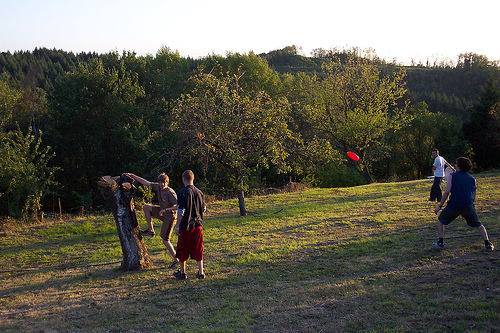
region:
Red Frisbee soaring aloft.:
[323, 131, 374, 185]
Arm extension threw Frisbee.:
[420, 140, 459, 216]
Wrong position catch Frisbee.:
[430, 158, 487, 266]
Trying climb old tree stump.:
[100, 165, 176, 276]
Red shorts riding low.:
[176, 170, 212, 281]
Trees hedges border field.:
[85, 63, 411, 190]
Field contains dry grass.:
[248, 195, 430, 321]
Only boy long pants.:
[416, 142, 453, 221]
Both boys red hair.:
[133, 165, 209, 191]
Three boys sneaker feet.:
[135, 224, 497, 284]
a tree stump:
[96, 173, 156, 270]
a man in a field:
[173, 165, 222, 289]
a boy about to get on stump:
[114, 154, 182, 257]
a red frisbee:
[342, 136, 363, 172]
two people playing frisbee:
[420, 141, 498, 274]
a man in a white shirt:
[426, 143, 453, 180]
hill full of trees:
[12, 34, 337, 153]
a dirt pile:
[276, 179, 314, 193]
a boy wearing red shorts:
[174, 165, 210, 297]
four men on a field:
[96, 144, 488, 286]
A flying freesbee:
[336, 140, 382, 198]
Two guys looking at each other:
[79, 150, 256, 259]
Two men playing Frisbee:
[331, 88, 492, 273]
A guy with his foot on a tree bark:
[87, 166, 175, 247]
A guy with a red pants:
[181, 168, 214, 297]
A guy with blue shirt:
[451, 157, 488, 262]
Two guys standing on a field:
[101, 154, 258, 291]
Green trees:
[35, 51, 374, 166]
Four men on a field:
[41, 82, 493, 319]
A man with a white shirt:
[418, 143, 445, 183]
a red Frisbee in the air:
[343, 149, 362, 164]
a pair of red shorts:
[173, 222, 205, 265]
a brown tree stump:
[96, 168, 158, 272]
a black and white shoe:
[431, 234, 448, 250]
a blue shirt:
[446, 170, 477, 206]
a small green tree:
[163, 60, 302, 219]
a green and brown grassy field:
[2, 167, 497, 331]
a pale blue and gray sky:
[1, 1, 498, 69]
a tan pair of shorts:
[143, 203, 176, 240]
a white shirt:
[430, 155, 450, 179]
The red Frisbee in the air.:
[343, 148, 364, 165]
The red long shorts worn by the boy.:
[178, 229, 205, 261]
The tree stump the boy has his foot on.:
[101, 171, 156, 272]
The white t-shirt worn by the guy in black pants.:
[426, 155, 446, 178]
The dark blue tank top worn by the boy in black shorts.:
[446, 173, 478, 208]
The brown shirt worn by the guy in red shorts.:
[178, 187, 204, 227]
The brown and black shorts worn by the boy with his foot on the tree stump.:
[146, 196, 175, 242]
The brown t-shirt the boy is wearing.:
[151, 186, 178, 213]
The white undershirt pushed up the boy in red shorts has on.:
[176, 207, 186, 214]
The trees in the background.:
[6, 48, 488, 222]